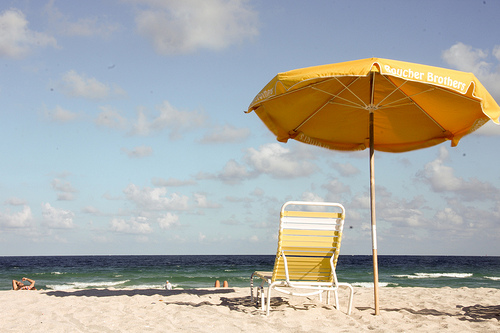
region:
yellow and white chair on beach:
[254, 196, 357, 324]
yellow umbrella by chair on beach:
[239, 52, 499, 156]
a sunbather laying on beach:
[9, 275, 39, 289]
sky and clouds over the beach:
[138, 177, 221, 220]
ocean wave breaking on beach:
[404, 264, 471, 282]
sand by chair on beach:
[123, 308, 240, 330]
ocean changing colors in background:
[141, 255, 200, 278]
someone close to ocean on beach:
[160, 272, 181, 288]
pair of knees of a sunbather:
[212, 277, 233, 288]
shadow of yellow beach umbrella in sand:
[380, 302, 498, 317]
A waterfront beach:
[75, 95, 426, 330]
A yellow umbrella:
[273, 62, 499, 189]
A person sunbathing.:
[11, 277, 56, 297]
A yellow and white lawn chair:
[266, 195, 348, 308]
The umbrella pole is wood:
[365, 170, 407, 302]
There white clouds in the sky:
[25, 90, 247, 237]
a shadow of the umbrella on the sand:
[56, 284, 214, 302]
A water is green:
[101, 268, 155, 276]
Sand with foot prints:
[252, 313, 304, 331]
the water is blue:
[125, 253, 184, 265]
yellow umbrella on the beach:
[240, 38, 475, 191]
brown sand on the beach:
[136, 291, 197, 331]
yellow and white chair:
[268, 193, 356, 297]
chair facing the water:
[260, 198, 353, 322]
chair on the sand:
[246, 195, 356, 312]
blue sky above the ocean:
[93, 148, 204, 235]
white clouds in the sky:
[120, 176, 210, 251]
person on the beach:
[9, 254, 52, 310]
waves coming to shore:
[407, 263, 471, 292]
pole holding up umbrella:
[360, 147, 399, 319]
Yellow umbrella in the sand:
[331, 48, 486, 319]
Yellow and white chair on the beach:
[234, 193, 369, 331]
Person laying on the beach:
[9, 268, 39, 301]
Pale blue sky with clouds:
[35, 50, 207, 227]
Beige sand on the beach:
[56, 288, 191, 328]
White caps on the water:
[393, 260, 486, 284]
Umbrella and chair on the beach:
[245, 91, 428, 324]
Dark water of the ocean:
[31, 257, 157, 277]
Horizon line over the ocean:
[61, 243, 193, 265]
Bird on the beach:
[151, 269, 186, 303]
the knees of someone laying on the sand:
[206, 272, 233, 298]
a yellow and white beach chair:
[257, 190, 359, 320]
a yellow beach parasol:
[255, 50, 499, 191]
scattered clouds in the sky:
[17, 160, 225, 250]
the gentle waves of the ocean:
[388, 253, 498, 295]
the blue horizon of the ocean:
[12, 233, 253, 268]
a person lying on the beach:
[10, 267, 45, 294]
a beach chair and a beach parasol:
[223, 39, 498, 311]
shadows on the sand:
[48, 287, 235, 332]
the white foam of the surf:
[394, 263, 494, 290]